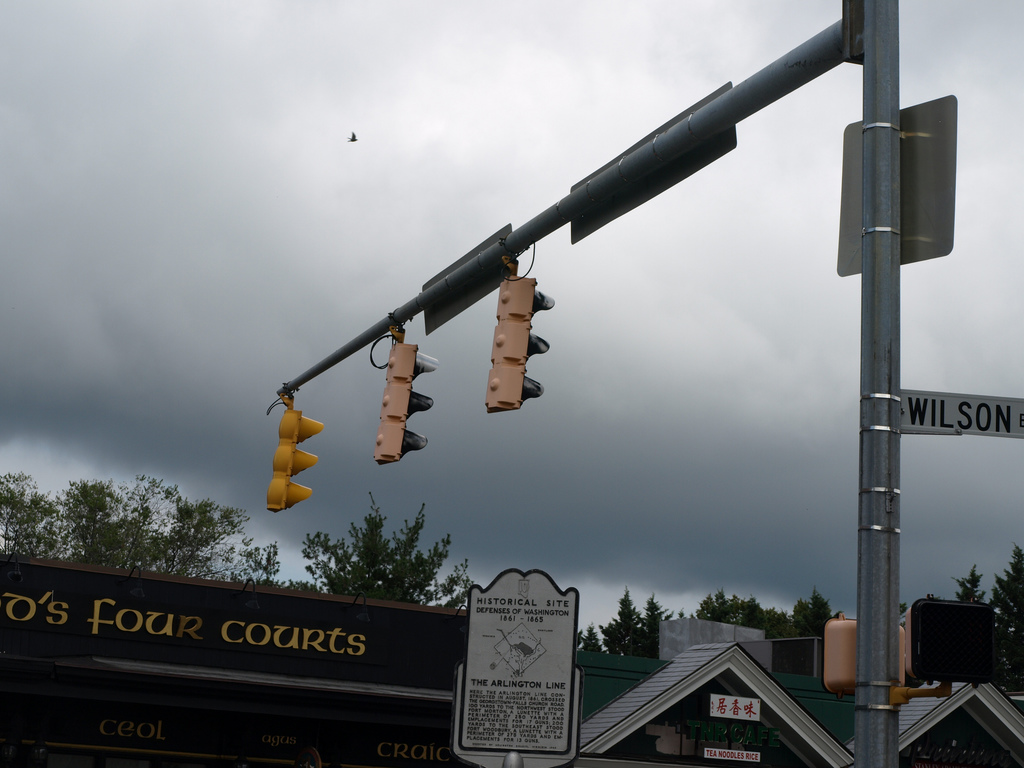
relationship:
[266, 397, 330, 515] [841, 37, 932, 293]
lights on pole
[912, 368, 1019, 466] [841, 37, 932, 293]
sign on pole